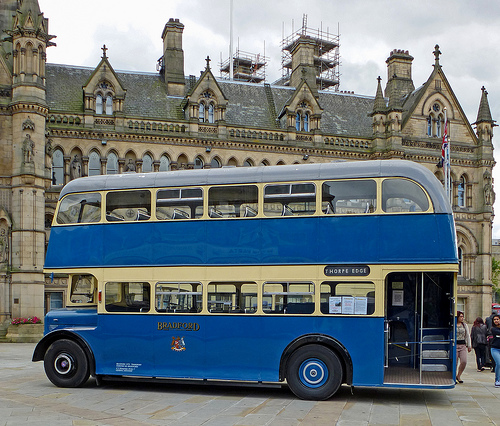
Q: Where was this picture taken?
A: London.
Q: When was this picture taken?
A: Daytime.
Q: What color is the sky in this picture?
A: Grey.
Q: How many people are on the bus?
A: Zero.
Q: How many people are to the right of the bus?
A: Three.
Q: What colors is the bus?
A: Blue and yellow.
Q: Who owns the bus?
A: Bradford.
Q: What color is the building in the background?
A: Tan.